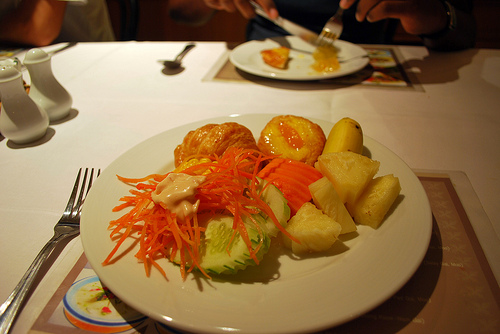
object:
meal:
[312, 150, 381, 205]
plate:
[79, 113, 435, 334]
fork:
[0, 167, 102, 332]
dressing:
[150, 172, 207, 222]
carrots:
[116, 174, 167, 184]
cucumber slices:
[164, 212, 261, 274]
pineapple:
[352, 173, 403, 230]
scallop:
[255, 114, 327, 168]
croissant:
[173, 121, 258, 168]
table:
[1, 38, 498, 333]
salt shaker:
[0, 59, 50, 146]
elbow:
[9, 4, 65, 48]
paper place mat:
[200, 44, 427, 92]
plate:
[228, 35, 374, 81]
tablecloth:
[0, 41, 499, 333]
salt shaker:
[22, 47, 73, 122]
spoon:
[156, 42, 196, 70]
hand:
[338, 0, 450, 37]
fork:
[314, 7, 350, 47]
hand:
[203, 2, 278, 21]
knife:
[249, 0, 342, 54]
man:
[201, 0, 479, 54]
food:
[260, 46, 290, 70]